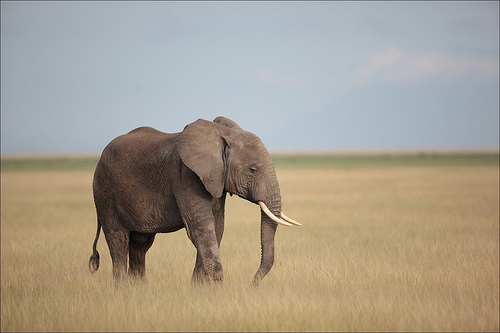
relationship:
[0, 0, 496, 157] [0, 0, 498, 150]
cloud in sky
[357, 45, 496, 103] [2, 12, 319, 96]
cloud in sky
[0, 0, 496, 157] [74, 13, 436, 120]
cloud in sky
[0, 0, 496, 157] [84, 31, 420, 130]
cloud in sky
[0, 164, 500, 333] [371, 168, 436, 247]
grass on ground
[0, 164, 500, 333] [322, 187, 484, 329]
grass on ground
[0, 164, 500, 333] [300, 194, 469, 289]
grass on ground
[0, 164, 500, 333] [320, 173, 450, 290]
grass on ground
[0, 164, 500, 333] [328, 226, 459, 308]
grass on ground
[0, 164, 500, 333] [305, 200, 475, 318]
grass with ground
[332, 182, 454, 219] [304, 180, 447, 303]
grass on ground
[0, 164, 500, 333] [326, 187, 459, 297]
grass on ground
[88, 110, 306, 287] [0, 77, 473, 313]
elephant in field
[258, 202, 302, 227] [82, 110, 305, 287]
tusks on elephant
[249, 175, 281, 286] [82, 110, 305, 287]
trunk of elephant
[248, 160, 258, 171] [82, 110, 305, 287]
right eye of elephant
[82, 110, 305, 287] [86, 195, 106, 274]
elephant has tail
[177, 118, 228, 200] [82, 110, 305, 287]
ear of elephant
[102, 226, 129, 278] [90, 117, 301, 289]
back leg of elephant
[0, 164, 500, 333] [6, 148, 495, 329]
grass in field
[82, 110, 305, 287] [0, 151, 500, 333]
elephant in plain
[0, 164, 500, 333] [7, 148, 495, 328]
grass in plain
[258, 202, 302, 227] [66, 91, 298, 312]
tusks of elephant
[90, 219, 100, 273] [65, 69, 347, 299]
tail on elephant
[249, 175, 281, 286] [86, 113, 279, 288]
trunk of elephant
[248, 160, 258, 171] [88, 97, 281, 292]
right eye of elephant